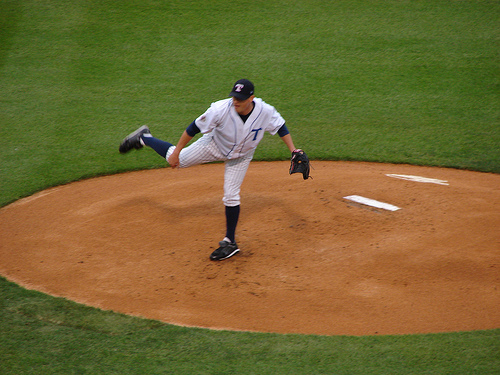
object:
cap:
[228, 78, 255, 100]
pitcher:
[118, 77, 311, 263]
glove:
[287, 147, 312, 181]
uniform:
[142, 97, 290, 239]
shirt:
[185, 120, 200, 139]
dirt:
[114, 214, 209, 273]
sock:
[224, 207, 241, 244]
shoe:
[118, 124, 153, 156]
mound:
[404, 184, 493, 229]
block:
[341, 192, 402, 211]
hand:
[165, 153, 181, 170]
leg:
[208, 161, 251, 262]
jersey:
[193, 98, 284, 160]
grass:
[186, 11, 330, 81]